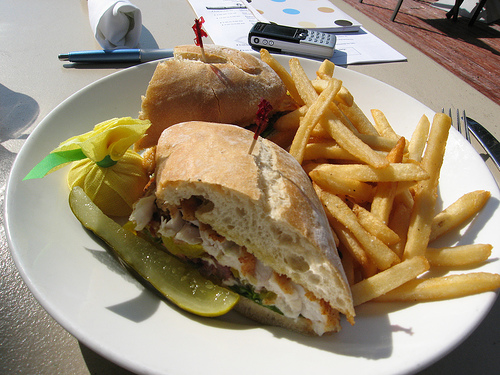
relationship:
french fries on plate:
[260, 47, 498, 307] [7, 42, 484, 369]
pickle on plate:
[67, 185, 240, 319] [7, 42, 484, 369]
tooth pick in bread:
[243, 100, 273, 162] [155, 120, 355, 327]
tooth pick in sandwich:
[188, 14, 208, 56] [135, 41, 294, 130]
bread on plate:
[155, 120, 355, 327] [7, 42, 484, 369]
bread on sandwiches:
[133, 45, 286, 153] [133, 39, 354, 340]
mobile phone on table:
[244, 17, 352, 62] [209, 1, 499, 152]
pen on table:
[57, 47, 187, 67] [1, 7, 60, 112]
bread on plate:
[133, 45, 286, 153] [7, 42, 484, 369]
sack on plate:
[53, 112, 163, 222] [7, 42, 484, 369]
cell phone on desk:
[247, 21, 337, 60] [0, 0, 499, 373]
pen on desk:
[57, 47, 187, 67] [0, 0, 499, 373]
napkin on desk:
[85, 0, 142, 50] [0, 0, 499, 373]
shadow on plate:
[345, 322, 392, 364] [7, 42, 484, 369]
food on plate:
[68, 40, 497, 334] [7, 42, 484, 369]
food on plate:
[68, 40, 497, 334] [36, 59, 496, 371]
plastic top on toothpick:
[192, 11, 209, 50] [183, 11, 235, 63]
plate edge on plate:
[2, 216, 157, 373] [94, 307, 184, 353]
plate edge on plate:
[2, 216, 157, 373] [42, 70, 413, 315]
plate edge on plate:
[2, 216, 157, 373] [7, 42, 484, 369]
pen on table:
[57, 47, 204, 67] [1, 0, 499, 372]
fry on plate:
[345, 254, 428, 306] [7, 42, 484, 369]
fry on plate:
[285, 51, 385, 170] [7, 42, 484, 369]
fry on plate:
[288, 74, 343, 164] [7, 42, 484, 369]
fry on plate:
[427, 238, 491, 268] [7, 42, 484, 369]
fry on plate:
[403, 107, 455, 211] [7, 42, 484, 369]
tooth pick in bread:
[247, 100, 273, 154] [157, 112, 362, 328]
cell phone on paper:
[247, 21, 337, 60] [332, 30, 382, 67]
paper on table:
[344, 32, 413, 72] [1, 0, 499, 372]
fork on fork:
[442, 108, 472, 146] [438, 105, 473, 149]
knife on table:
[467, 109, 498, 186] [1, 0, 499, 372]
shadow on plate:
[104, 286, 163, 324] [101, 322, 358, 371]